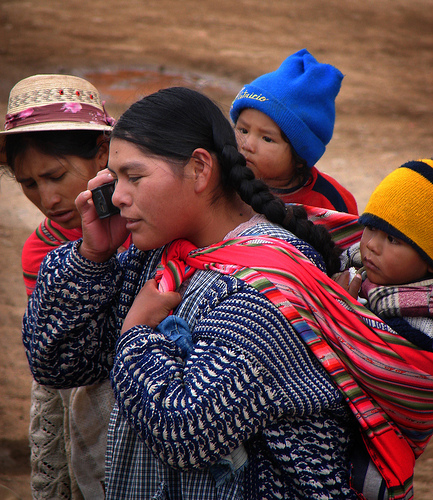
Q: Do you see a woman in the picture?
A: Yes, there is a woman.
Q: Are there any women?
A: Yes, there is a woman.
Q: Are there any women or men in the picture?
A: Yes, there is a woman.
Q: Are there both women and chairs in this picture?
A: No, there is a woman but no chairs.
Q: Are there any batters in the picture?
A: No, there are no batters.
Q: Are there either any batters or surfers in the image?
A: No, there are no batters or surfers.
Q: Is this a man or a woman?
A: This is a woman.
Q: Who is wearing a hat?
A: The woman is wearing a hat.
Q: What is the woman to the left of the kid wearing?
A: The woman is wearing a hat.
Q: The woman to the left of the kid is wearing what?
A: The woman is wearing a hat.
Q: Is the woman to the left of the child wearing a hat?
A: Yes, the woman is wearing a hat.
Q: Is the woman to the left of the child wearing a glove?
A: No, the woman is wearing a hat.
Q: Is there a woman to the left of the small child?
A: Yes, there is a woman to the left of the kid.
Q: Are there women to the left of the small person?
A: Yes, there is a woman to the left of the kid.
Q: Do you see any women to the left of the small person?
A: Yes, there is a woman to the left of the kid.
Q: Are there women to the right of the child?
A: No, the woman is to the left of the child.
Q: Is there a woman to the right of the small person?
A: No, the woman is to the left of the child.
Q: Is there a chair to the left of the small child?
A: No, there is a woman to the left of the kid.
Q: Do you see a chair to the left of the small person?
A: No, there is a woman to the left of the kid.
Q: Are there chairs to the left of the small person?
A: No, there is a woman to the left of the kid.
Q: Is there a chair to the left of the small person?
A: No, there is a woman to the left of the kid.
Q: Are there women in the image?
A: Yes, there is a woman.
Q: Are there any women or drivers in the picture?
A: Yes, there is a woman.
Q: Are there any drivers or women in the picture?
A: Yes, there is a woman.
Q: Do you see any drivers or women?
A: Yes, there is a woman.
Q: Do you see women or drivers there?
A: Yes, there is a woman.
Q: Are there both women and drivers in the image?
A: No, there is a woman but no drivers.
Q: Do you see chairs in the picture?
A: No, there are no chairs.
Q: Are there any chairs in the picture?
A: No, there are no chairs.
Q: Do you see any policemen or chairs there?
A: No, there are no chairs or policemen.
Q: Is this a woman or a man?
A: This is a woman.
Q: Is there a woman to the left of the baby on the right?
A: Yes, there is a woman to the left of the baby.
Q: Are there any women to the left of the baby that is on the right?
A: Yes, there is a woman to the left of the baby.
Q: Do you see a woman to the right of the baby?
A: No, the woman is to the left of the baby.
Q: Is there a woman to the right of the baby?
A: No, the woman is to the left of the baby.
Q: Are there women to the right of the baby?
A: No, the woman is to the left of the baby.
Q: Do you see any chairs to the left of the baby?
A: No, there is a woman to the left of the baby.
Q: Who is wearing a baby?
A: The woman is wearing a baby.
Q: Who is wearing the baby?
A: The woman is wearing a baby.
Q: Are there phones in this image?
A: Yes, there is a phone.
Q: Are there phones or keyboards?
A: Yes, there is a phone.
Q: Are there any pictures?
A: No, there are no pictures.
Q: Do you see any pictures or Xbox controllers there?
A: No, there are no pictures or Xbox controllers.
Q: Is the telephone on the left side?
A: Yes, the telephone is on the left of the image.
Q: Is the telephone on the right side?
A: No, the telephone is on the left of the image.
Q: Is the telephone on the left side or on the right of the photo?
A: The telephone is on the left of the image.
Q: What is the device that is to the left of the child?
A: The device is a phone.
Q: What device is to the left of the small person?
A: The device is a phone.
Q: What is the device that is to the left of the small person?
A: The device is a phone.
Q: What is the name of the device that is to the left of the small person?
A: The device is a phone.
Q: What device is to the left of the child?
A: The device is a phone.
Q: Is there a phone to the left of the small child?
A: Yes, there is a phone to the left of the child.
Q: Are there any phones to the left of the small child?
A: Yes, there is a phone to the left of the child.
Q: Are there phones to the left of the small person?
A: Yes, there is a phone to the left of the child.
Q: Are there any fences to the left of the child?
A: No, there is a phone to the left of the child.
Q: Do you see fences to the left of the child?
A: No, there is a phone to the left of the child.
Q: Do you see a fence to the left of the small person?
A: No, there is a phone to the left of the child.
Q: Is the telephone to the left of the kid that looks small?
A: Yes, the telephone is to the left of the child.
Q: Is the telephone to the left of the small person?
A: Yes, the telephone is to the left of the child.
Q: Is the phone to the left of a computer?
A: No, the phone is to the left of the child.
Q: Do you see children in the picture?
A: Yes, there is a child.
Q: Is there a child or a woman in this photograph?
A: Yes, there is a child.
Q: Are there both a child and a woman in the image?
A: Yes, there are both a child and a woman.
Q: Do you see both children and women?
A: Yes, there are both a child and a woman.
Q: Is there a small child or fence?
A: Yes, there is a small child.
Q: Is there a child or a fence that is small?
A: Yes, the child is small.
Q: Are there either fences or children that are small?
A: Yes, the child is small.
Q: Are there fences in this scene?
A: No, there are no fences.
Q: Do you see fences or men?
A: No, there are no fences or men.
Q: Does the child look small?
A: Yes, the child is small.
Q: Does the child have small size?
A: Yes, the child is small.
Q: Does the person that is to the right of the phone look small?
A: Yes, the child is small.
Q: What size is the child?
A: The child is small.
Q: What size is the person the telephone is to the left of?
A: The child is small.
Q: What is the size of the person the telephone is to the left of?
A: The child is small.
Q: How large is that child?
A: The child is small.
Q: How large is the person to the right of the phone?
A: The child is small.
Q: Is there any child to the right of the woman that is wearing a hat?
A: Yes, there is a child to the right of the woman.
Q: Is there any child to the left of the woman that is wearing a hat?
A: No, the child is to the right of the woman.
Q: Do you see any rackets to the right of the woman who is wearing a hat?
A: No, there is a child to the right of the woman.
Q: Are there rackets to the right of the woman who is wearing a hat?
A: No, there is a child to the right of the woman.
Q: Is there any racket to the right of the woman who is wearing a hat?
A: No, there is a child to the right of the woman.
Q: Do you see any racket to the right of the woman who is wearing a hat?
A: No, there is a child to the right of the woman.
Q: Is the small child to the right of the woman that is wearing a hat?
A: Yes, the child is to the right of the woman.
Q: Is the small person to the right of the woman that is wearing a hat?
A: Yes, the child is to the right of the woman.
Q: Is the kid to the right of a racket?
A: No, the kid is to the right of the woman.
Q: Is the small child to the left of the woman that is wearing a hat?
A: No, the kid is to the right of the woman.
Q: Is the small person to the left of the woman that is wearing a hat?
A: No, the kid is to the right of the woman.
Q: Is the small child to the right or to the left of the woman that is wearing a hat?
A: The kid is to the right of the woman.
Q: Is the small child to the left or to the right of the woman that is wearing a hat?
A: The kid is to the right of the woman.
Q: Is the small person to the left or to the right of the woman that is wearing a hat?
A: The kid is to the right of the woman.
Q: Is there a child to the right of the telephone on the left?
A: Yes, there is a child to the right of the phone.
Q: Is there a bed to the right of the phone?
A: No, there is a child to the right of the phone.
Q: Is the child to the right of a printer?
A: No, the child is to the right of the phone.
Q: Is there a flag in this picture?
A: No, there are no flags.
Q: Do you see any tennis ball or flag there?
A: No, there are no flags or tennis balls.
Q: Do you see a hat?
A: Yes, there is a hat.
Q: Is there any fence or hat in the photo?
A: Yes, there is a hat.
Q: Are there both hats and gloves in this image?
A: No, there is a hat but no gloves.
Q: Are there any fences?
A: No, there are no fences.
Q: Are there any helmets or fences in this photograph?
A: No, there are no fences or helmets.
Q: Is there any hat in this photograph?
A: Yes, there is a hat.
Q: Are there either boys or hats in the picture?
A: Yes, there is a hat.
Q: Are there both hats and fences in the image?
A: No, there is a hat but no fences.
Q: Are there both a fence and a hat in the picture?
A: No, there is a hat but no fences.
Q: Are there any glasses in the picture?
A: No, there are no glasses.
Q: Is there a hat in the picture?
A: Yes, there is a hat.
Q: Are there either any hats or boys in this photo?
A: Yes, there is a hat.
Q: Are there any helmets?
A: No, there are no helmets.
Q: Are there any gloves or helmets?
A: No, there are no helmets or gloves.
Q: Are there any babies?
A: Yes, there is a baby.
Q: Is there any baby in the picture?
A: Yes, there is a baby.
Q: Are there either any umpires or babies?
A: Yes, there is a baby.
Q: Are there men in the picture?
A: No, there are no men.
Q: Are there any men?
A: No, there are no men.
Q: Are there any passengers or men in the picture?
A: No, there are no men or passengers.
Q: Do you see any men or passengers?
A: No, there are no men or passengers.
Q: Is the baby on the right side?
A: Yes, the baby is on the right of the image.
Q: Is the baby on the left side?
A: No, the baby is on the right of the image.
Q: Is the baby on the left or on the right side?
A: The baby is on the right of the image.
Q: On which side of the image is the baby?
A: The baby is on the right of the image.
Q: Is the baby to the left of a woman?
A: No, the baby is to the right of a woman.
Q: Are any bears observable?
A: No, there are no bears.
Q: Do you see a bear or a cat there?
A: No, there are no bears or cats.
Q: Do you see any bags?
A: No, there are no bags.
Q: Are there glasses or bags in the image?
A: No, there are no bags or glasses.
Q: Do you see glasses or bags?
A: No, there are no bags or glasses.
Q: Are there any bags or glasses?
A: No, there are no bags or glasses.